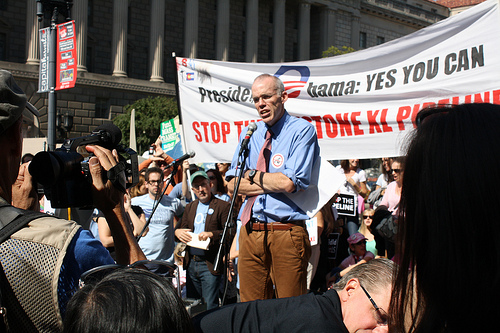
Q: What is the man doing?
A: Giving a speech.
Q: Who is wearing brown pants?
A: Man talking.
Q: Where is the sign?
A: Behind the man on stage.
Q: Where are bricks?
A: On a building.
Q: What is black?
A: Video camera.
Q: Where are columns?
A: On a building.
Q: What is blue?
A: Shirt on the man talking.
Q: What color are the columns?
A: White.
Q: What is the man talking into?
A: Microphone.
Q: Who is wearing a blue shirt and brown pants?
A: The man talking into the microphone.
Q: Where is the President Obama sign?
A: Behind the man in the blue shirt.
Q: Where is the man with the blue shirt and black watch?
A: Behind the microphone.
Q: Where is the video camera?
A: On the left side, pointing at the man who is speaking.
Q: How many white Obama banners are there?
A: One.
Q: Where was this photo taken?
A: Outside at a political event.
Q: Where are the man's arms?
A: Folded in front of him.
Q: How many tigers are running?
A: Zero.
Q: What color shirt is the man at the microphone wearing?
A: Light blue.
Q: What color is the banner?
A: White.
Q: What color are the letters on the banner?
A: Black and red.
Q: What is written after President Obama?
A: Yes You Can.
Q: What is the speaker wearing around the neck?
A: A tie.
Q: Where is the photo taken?
A: At a protest.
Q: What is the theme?
A: Putting a halt Keystone.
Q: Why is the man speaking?
A: To rally support.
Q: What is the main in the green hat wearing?
A: A brown blazer.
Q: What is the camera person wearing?
A: A blue shirt.